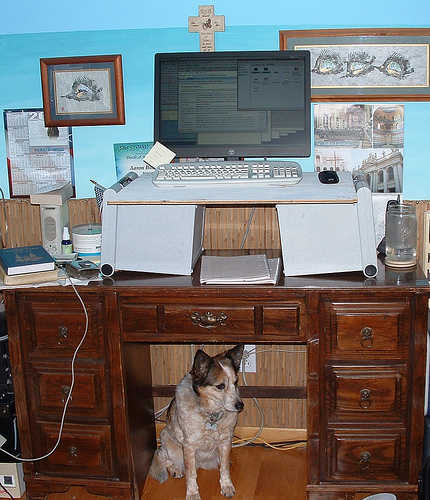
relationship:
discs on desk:
[72, 230, 102, 253] [12, 278, 424, 493]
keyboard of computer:
[161, 164, 293, 184] [102, 47, 379, 277]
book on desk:
[5, 233, 71, 295] [4, 248, 429, 498]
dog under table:
[145, 334, 250, 498] [7, 242, 429, 495]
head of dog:
[185, 344, 256, 430] [149, 342, 246, 500]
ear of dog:
[187, 342, 217, 385] [144, 342, 318, 488]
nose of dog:
[228, 392, 255, 420] [150, 332, 282, 498]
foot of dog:
[184, 492, 201, 498] [145, 340, 234, 497]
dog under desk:
[145, 334, 250, 498] [2, 249, 430, 500]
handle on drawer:
[357, 388, 374, 410] [323, 361, 408, 421]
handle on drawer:
[358, 326, 374, 352] [322, 300, 413, 360]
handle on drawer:
[353, 450, 374, 472] [321, 420, 413, 482]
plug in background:
[236, 343, 256, 372] [144, 345, 312, 451]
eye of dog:
[212, 383, 229, 394] [145, 334, 250, 498]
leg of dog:
[182, 441, 199, 498] [149, 342, 246, 500]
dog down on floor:
[149, 342, 246, 500] [1, 436, 310, 497]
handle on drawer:
[192, 308, 228, 331] [123, 297, 298, 344]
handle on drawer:
[360, 327, 374, 348] [322, 300, 413, 360]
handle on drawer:
[358, 451, 373, 472] [321, 420, 413, 482]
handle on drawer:
[52, 324, 71, 350] [24, 298, 105, 362]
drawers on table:
[320, 297, 420, 488] [21, 210, 419, 332]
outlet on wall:
[236, 342, 265, 377] [243, 341, 304, 430]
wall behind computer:
[5, 4, 428, 242] [148, 47, 314, 188]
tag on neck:
[207, 409, 224, 424] [184, 374, 242, 438]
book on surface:
[3, 246, 56, 274] [7, 234, 423, 280]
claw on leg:
[216, 482, 235, 499] [213, 416, 236, 485]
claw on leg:
[178, 483, 205, 495] [178, 425, 207, 484]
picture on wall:
[281, 25, 427, 98] [2, 3, 428, 203]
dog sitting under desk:
[149, 342, 246, 500] [4, 248, 429, 498]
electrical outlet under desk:
[234, 342, 262, 373] [4, 248, 429, 498]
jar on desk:
[380, 200, 423, 265] [12, 278, 424, 493]